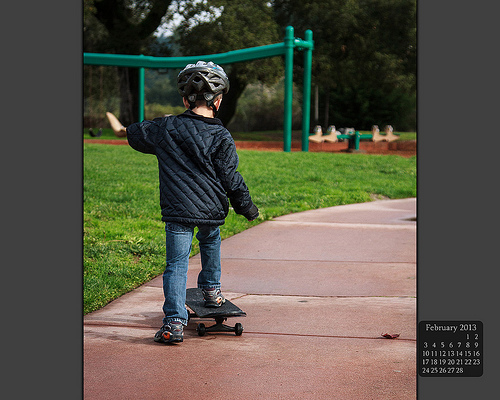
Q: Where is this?
A: This is at the park.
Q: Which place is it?
A: It is a park.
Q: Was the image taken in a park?
A: Yes, it was taken in a park.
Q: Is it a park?
A: Yes, it is a park.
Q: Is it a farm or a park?
A: It is a park.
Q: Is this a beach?
A: No, it is a park.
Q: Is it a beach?
A: No, it is a park.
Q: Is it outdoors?
A: Yes, it is outdoors.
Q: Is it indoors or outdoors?
A: It is outdoors.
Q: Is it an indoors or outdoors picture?
A: It is outdoors.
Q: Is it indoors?
A: No, it is outdoors.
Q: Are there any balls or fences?
A: No, there are no fences or balls.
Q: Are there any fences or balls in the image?
A: No, there are no fences or balls.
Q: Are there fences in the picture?
A: No, there are no fences.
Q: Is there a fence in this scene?
A: No, there are no fences.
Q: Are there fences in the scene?
A: No, there are no fences.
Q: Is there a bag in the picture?
A: No, there are no bags.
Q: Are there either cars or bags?
A: No, there are no bags or cars.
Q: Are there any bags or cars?
A: No, there are no bags or cars.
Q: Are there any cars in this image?
A: No, there are no cars.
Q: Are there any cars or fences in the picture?
A: No, there are no cars or fences.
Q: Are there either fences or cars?
A: No, there are no cars or fences.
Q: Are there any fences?
A: No, there are no fences.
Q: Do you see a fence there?
A: No, there are no fences.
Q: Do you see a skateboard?
A: Yes, there is a skateboard.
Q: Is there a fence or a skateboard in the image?
A: Yes, there is a skateboard.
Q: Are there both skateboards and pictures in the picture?
A: No, there is a skateboard but no pictures.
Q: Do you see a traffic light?
A: No, there are no traffic lights.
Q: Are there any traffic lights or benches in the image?
A: No, there are no traffic lights or benches.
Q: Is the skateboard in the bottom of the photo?
A: Yes, the skateboard is in the bottom of the image.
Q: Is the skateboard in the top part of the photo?
A: No, the skateboard is in the bottom of the image.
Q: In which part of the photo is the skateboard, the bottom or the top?
A: The skateboard is in the bottom of the image.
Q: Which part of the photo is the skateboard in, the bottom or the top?
A: The skateboard is in the bottom of the image.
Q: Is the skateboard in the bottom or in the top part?
A: The skateboard is in the bottom of the image.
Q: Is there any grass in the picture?
A: Yes, there is grass.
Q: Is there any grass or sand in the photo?
A: Yes, there is grass.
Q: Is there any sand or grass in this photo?
A: Yes, there is grass.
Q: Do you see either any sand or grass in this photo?
A: Yes, there is grass.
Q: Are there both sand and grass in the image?
A: No, there is grass but no sand.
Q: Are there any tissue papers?
A: No, there are no tissue papers.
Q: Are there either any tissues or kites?
A: No, there are no tissues or kites.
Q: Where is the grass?
A: The grass is on the ground.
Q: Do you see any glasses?
A: No, there are no glasses.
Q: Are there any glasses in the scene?
A: No, there are no glasses.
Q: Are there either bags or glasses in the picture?
A: No, there are no glasses or bags.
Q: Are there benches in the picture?
A: No, there are no benches.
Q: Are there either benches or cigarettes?
A: No, there are no benches or cigarettes.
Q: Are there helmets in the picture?
A: Yes, there is a helmet.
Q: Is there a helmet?
A: Yes, there is a helmet.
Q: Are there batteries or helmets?
A: Yes, there is a helmet.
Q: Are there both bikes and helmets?
A: No, there is a helmet but no bikes.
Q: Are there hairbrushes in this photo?
A: No, there are no hairbrushes.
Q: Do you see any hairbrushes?
A: No, there are no hairbrushes.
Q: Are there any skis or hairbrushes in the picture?
A: No, there are no hairbrushes or skis.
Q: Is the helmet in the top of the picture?
A: Yes, the helmet is in the top of the image.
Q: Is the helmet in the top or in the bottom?
A: The helmet is in the top of the image.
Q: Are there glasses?
A: No, there are no glasses.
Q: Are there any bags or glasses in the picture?
A: No, there are no glasses or bags.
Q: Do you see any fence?
A: No, there are no fences.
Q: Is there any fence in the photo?
A: No, there are no fences.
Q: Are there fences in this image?
A: No, there are no fences.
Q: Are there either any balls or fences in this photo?
A: No, there are no fences or balls.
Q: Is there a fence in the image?
A: No, there are no fences.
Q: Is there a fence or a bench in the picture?
A: No, there are no fences or benches.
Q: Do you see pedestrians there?
A: No, there are no pedestrians.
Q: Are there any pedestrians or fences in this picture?
A: No, there are no pedestrians or fences.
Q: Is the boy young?
A: Yes, the boy is young.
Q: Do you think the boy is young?
A: Yes, the boy is young.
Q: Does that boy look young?
A: Yes, the boy is young.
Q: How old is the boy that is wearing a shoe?
A: The boy is young.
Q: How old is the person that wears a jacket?
A: The boy is young.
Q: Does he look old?
A: No, the boy is young.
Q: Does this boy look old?
A: No, the boy is young.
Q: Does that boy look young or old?
A: The boy is young.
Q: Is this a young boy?
A: Yes, this is a young boy.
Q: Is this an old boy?
A: No, this is a young boy.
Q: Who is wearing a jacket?
A: The boy is wearing a jacket.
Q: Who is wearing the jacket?
A: The boy is wearing a jacket.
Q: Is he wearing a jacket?
A: Yes, the boy is wearing a jacket.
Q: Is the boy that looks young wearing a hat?
A: No, the boy is wearing a jacket.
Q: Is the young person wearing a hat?
A: No, the boy is wearing a jacket.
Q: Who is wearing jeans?
A: The boy is wearing jeans.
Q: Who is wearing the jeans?
A: The boy is wearing jeans.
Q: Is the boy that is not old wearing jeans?
A: Yes, the boy is wearing jeans.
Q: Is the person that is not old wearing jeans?
A: Yes, the boy is wearing jeans.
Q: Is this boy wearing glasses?
A: No, the boy is wearing jeans.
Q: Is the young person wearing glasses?
A: No, the boy is wearing jeans.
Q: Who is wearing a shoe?
A: The boy is wearing a shoe.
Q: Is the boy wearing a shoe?
A: Yes, the boy is wearing a shoe.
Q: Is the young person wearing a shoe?
A: Yes, the boy is wearing a shoe.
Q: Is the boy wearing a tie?
A: No, the boy is wearing a shoe.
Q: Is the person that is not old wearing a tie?
A: No, the boy is wearing a shoe.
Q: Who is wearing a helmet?
A: The boy is wearing a helmet.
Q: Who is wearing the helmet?
A: The boy is wearing a helmet.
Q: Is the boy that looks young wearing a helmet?
A: Yes, the boy is wearing a helmet.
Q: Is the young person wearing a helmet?
A: Yes, the boy is wearing a helmet.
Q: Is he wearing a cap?
A: No, the boy is wearing a helmet.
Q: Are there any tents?
A: No, there are no tents.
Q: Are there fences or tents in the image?
A: No, there are no tents or fences.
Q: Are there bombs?
A: No, there are no bombs.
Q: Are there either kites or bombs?
A: No, there are no bombs or kites.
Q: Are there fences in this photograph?
A: No, there are no fences.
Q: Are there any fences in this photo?
A: No, there are no fences.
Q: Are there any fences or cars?
A: No, there are no fences or cars.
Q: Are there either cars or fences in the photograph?
A: No, there are no fences or cars.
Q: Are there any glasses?
A: No, there are no glasses.